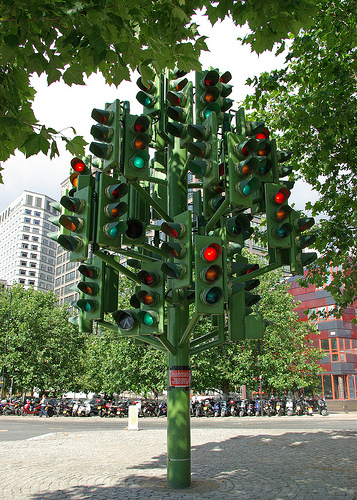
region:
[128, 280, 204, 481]
pole with traffic lights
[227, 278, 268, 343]
side of traffic light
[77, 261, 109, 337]
side of traffic light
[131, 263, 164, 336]
traffic light on pole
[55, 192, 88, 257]
traffic light on pole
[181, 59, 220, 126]
traffic light on pole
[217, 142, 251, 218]
traffic light on pole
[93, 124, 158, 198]
traffic light on pole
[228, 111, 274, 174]
traffic light on pole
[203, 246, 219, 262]
red colored traffic signal light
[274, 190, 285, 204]
red colored traffic signal light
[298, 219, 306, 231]
red colored traffic signal light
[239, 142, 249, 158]
red colored traffic signal light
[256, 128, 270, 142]
red colored traffic signal light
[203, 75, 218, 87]
red colored traffic signal light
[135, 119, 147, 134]
red colored traffic signal light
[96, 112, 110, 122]
red colored traffic signal light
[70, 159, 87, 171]
red colored traffic signal light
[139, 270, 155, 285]
red colored traffic signal light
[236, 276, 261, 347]
traffic light on pole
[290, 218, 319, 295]
traffic light on pole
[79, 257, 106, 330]
traffic light on pole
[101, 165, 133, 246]
traffic pole on light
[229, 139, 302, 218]
traffic light on pole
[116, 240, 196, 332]
traffic light on pole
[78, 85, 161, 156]
traffic light on pole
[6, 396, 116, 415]
bikes parked at distance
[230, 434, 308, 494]
shadow of tree falling on ground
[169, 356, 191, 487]
green color pole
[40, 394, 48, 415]
man visible walking from background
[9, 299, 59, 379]
trees visible at background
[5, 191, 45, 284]
white color building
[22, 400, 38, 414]
red color bike visible from distance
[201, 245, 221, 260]
red light lighted on signal pannel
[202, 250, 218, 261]
red colored traffic light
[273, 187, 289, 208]
red colored traffic light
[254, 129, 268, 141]
red colored traffic light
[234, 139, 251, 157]
red colored traffic light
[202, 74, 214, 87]
red colored traffic light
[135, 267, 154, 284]
red colored traffic light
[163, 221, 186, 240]
red colored traffic light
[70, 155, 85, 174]
red colored traffic light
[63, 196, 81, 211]
red colored traffic light